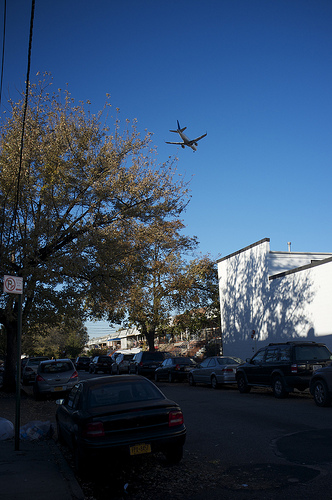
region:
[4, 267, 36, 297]
A no-parking sign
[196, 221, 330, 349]
a white building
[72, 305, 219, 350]
A row of small buildings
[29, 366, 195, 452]
A car on a street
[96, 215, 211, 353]
A tree in the city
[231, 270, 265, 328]
The shadow of a tree on a building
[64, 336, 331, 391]
A row of parked cars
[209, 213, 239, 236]
A section of blue sky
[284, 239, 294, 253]
A smokestack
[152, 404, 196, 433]
The taillight of a car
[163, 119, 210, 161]
an airplane flying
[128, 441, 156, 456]
a yellow license plate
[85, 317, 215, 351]
row of houses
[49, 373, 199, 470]
a parked car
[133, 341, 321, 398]
a row of parked cars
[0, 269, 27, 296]
a no parking sign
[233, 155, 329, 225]
clear blue skys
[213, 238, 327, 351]
a tall white building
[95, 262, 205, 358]
a green tree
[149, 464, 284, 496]
a pile of leaves on ground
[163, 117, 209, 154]
Airplane in the sky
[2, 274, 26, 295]
No parking sign on a pole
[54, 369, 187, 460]
Car with a yellow license plate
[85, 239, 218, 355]
Tree on far side of road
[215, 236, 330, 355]
White building with black trim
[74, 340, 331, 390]
Many cars parked in a row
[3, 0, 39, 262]
Wire stretching across poles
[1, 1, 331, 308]
Blue sky on a clear day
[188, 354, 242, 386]
Silver car parked in front of SUV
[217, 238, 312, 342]
Shadow of tree on building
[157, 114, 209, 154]
a jet flying overhead in a blue sky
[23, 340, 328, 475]
cars are parked on both sides of the road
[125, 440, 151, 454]
the car has a new york tag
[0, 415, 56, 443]
boulders are on the sidewalk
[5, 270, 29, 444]
a no parking sign is on a pole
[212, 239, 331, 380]
a white building with a smoke stack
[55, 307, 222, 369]
a two story building is near the street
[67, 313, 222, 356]
the building has many windows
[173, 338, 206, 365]
cement steps go up to the second floor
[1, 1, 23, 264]
power lines are near the trees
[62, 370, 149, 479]
A car is visible.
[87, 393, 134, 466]
A car is visible.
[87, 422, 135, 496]
A car is visible.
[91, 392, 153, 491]
A car is visible.